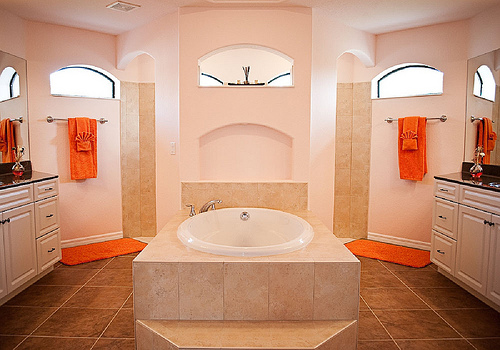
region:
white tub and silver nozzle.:
[180, 182, 296, 262]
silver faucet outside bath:
[180, 177, 240, 228]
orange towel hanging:
[366, 105, 436, 195]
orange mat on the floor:
[60, 220, 135, 280]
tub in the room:
[155, 157, 345, 298]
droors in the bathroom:
[33, 176, 63, 275]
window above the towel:
[377, 41, 466, 106]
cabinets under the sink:
[1, 205, 37, 262]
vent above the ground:
[99, 1, 145, 26]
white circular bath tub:
[177, 202, 316, 267]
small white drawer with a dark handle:
[431, 199, 457, 230]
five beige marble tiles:
[138, 264, 355, 319]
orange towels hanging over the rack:
[64, 115, 104, 185]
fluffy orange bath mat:
[53, 227, 145, 266]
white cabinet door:
[448, 201, 498, 291]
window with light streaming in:
[366, 58, 448, 109]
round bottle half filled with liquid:
[465, 157, 485, 182]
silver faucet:
[199, 196, 223, 213]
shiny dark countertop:
[436, 155, 499, 192]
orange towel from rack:
[69, 117, 96, 177]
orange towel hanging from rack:
[397, 117, 425, 179]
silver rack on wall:
[47, 117, 108, 124]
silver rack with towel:
[385, 114, 448, 121]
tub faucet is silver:
[196, 200, 222, 215]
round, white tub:
[177, 206, 309, 247]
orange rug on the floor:
[58, 235, 144, 263]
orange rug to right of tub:
[345, 236, 430, 264]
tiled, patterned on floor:
[0, 238, 496, 346]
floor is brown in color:
[1, 238, 498, 348]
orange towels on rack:
[379, 102, 449, 189]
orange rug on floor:
[341, 225, 441, 273]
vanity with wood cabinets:
[425, 159, 498, 298]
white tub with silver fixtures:
[171, 199, 318, 271]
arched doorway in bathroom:
[320, 43, 375, 245]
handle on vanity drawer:
[431, 208, 458, 230]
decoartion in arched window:
[219, 59, 281, 95]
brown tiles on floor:
[34, 279, 117, 336]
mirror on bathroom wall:
[460, 47, 496, 173]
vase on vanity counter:
[464, 143, 491, 181]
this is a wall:
[213, 86, 284, 123]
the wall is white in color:
[199, 92, 301, 122]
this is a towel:
[71, 115, 100, 177]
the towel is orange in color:
[69, 150, 97, 180]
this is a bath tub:
[185, 205, 315, 259]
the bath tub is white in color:
[207, 227, 275, 244]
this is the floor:
[43, 286, 113, 348]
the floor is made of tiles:
[56, 279, 113, 346]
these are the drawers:
[433, 182, 455, 264]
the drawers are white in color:
[451, 231, 498, 283]